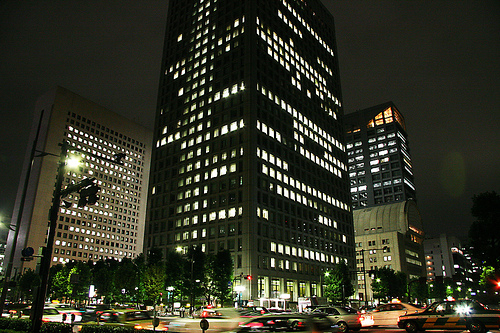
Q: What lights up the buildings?
A: Interior lights.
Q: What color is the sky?
A: Black.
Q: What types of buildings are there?
A: Skyscrapers.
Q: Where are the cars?
A: In the street.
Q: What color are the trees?
A: Green.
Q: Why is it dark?
A: It is nighttime.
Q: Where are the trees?
A: Along the road.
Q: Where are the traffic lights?
A: Hanging over the street.